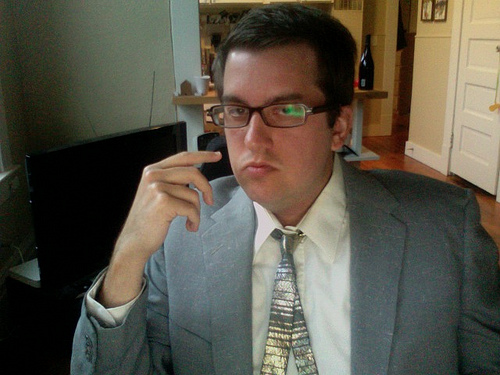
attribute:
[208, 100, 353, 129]
glasses — black, dark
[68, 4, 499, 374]
man. — white, thinking, staring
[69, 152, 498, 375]
suit — gray, grey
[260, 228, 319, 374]
tie — silver, shiny, unkempt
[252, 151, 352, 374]
shirt — white, dressy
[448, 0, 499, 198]
door — white, wooden, closed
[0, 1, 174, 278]
wall — tan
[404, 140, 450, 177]
base board — white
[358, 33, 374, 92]
bottle — shiny, black, dark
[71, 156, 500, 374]
suit coat — gray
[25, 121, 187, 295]
screen — flat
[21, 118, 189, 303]
tv — flat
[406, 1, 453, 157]
wall — yellow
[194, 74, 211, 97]
cup — white, paper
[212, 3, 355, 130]
hair — brown, short, well-groomed, dark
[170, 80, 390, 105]
counter — wooden